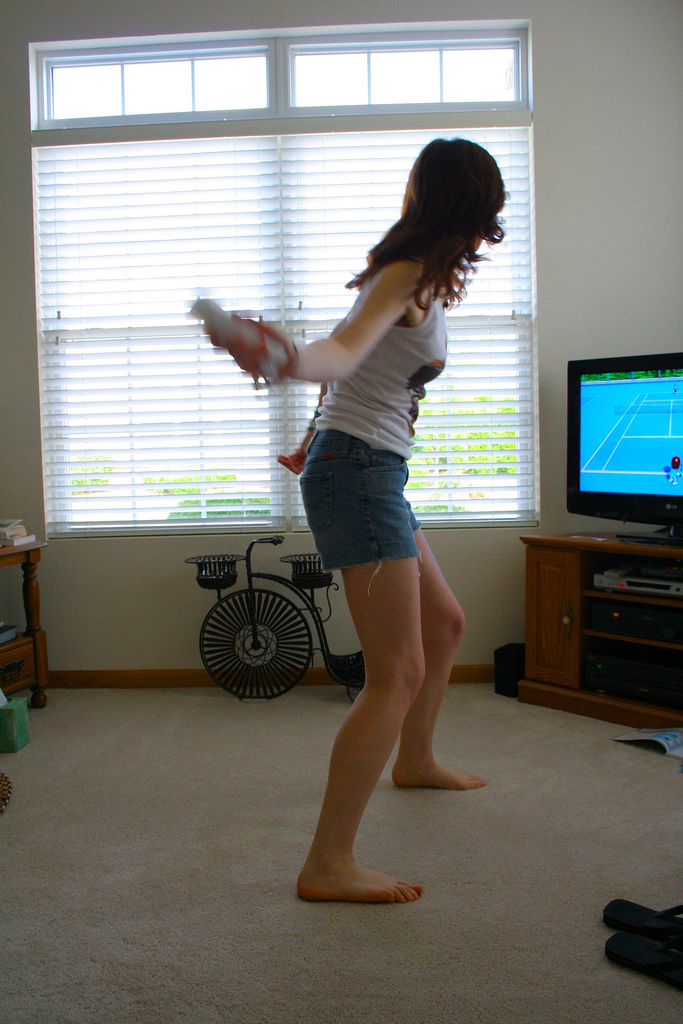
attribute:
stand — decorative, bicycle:
[182, 532, 366, 704]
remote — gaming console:
[186, 296, 292, 381]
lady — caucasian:
[200, 138, 508, 901]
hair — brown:
[347, 137, 510, 316]